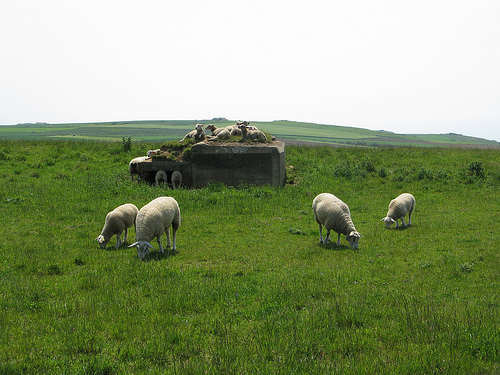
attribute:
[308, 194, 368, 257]
sheep — grazing, white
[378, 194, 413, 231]
sheep — grazing, white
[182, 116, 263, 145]
sheep — resting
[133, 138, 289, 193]
structure — concrete, bunker, cement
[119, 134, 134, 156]
plant — green, small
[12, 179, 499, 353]
grass — tall, green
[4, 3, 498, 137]
sky — white, bright